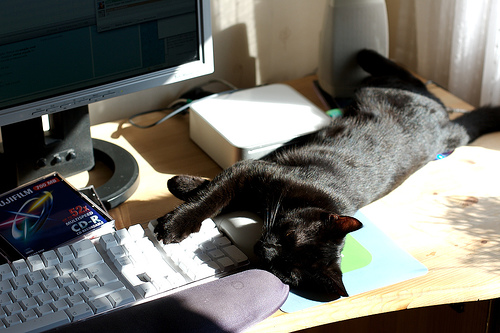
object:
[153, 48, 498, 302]
cat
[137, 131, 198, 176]
table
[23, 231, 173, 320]
keyboard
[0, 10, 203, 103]
monitor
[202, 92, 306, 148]
router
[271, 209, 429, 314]
mouse pad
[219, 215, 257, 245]
mouse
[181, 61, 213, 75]
sunlight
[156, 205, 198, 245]
paw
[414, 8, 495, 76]
curtain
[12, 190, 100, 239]
case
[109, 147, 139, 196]
base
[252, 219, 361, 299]
head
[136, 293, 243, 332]
wrist pad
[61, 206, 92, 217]
print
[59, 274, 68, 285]
key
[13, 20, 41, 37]
screen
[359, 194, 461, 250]
sunlight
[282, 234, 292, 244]
eye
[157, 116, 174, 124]
cord